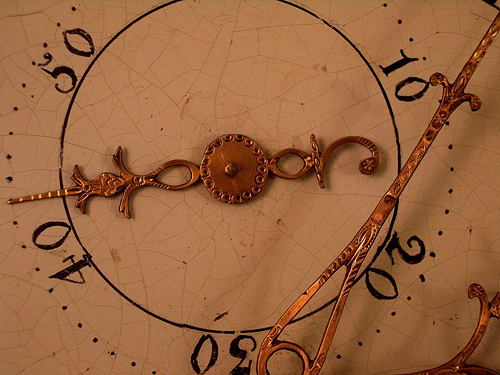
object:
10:
[377, 49, 431, 103]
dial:
[5, 133, 382, 221]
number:
[34, 51, 79, 94]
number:
[61, 26, 95, 57]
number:
[377, 48, 419, 77]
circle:
[57, 0, 403, 335]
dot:
[22, 82, 26, 86]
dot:
[72, 5, 76, 11]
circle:
[199, 133, 271, 205]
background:
[0, 2, 498, 374]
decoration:
[411, 282, 500, 374]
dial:
[256, 13, 499, 374]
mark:
[109, 247, 123, 262]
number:
[393, 76, 428, 102]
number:
[47, 251, 91, 285]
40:
[31, 220, 94, 285]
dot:
[422, 55, 427, 61]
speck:
[322, 64, 327, 73]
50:
[38, 28, 96, 94]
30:
[190, 333, 258, 373]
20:
[364, 228, 426, 300]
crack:
[178, 26, 222, 104]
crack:
[329, 73, 358, 101]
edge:
[58, 145, 66, 171]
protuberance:
[178, 322, 187, 329]